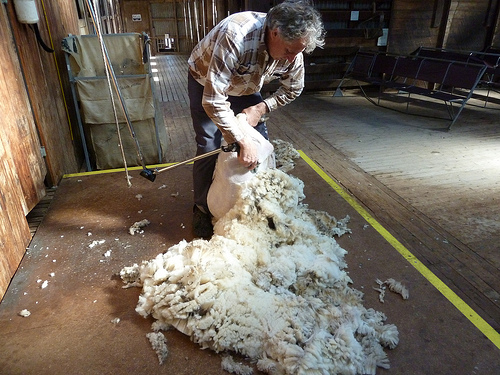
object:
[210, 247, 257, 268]
fur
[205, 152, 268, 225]
sheep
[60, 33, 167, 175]
bag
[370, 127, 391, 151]
floor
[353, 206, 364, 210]
line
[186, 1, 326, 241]
man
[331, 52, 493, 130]
chairs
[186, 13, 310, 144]
shirt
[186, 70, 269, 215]
jeans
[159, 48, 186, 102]
hallway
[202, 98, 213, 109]
elbow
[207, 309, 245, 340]
wool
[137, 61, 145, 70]
cloth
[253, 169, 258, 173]
tool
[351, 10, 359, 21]
sign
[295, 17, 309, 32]
hair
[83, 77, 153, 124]
bin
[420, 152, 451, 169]
sunlight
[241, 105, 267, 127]
hand